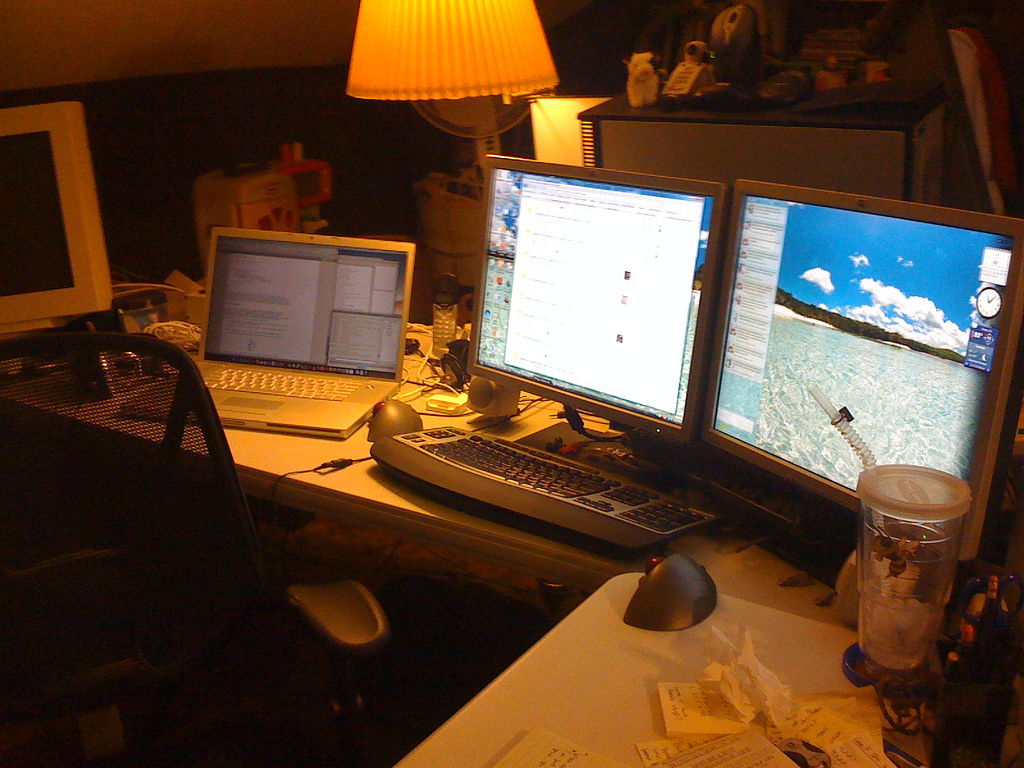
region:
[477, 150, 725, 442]
monitor is on a desk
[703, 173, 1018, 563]
monitor is on a desk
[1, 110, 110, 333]
monitor is on a desk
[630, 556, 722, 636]
mouse is gray and round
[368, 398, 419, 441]
mouse is gray and round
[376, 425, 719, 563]
keyboard is on a table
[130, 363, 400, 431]
keyboard is on a table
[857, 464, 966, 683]
plastic cup is on a table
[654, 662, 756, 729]
paper is on a table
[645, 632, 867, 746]
White receipt on the desk top.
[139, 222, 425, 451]
Silver open laptop on desk.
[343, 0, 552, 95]
White pleated lamp shade.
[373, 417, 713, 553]
Keyboard with black keys.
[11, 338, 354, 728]
Black computer chair.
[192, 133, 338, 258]
White sewing machine in corner.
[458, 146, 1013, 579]
Two monitors side by side turned on.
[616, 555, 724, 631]
A black computer mouse.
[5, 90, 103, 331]
An older white monitor.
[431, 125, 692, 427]
a white page is up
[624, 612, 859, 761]
receipts on the table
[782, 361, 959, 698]
the cup is clear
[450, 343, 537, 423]
the speaker is behind the monitor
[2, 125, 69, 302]
computer screen on the white desk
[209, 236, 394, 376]
computer screen on the white desk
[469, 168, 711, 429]
computer screen on the white desk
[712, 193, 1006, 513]
computer screen on the white desk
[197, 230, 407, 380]
computer screen on the white desk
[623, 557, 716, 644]
grey mouse on the white desk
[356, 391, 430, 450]
grey mouse on the white desk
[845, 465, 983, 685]
clear cup on the white desk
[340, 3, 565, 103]
large round white shade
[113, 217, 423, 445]
large silver square laptop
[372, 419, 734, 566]
long thin black keyboard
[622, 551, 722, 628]
large round black mouse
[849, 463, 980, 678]
tall clear plastic cup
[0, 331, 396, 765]
large black cloth chair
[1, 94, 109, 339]
large square white screen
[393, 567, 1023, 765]
large square white table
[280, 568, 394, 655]
thick black long arm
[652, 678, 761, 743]
small square white paper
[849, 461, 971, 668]
the cup is clear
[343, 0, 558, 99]
the lamp shade is white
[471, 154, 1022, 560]
the monitors are side by side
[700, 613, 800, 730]
the paper is crumpled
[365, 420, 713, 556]
the keyboard is black and gray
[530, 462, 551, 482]
A key on a keyboard.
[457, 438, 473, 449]
A key on a keyboard.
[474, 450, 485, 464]
A key on a keyboard.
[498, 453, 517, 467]
A key on a keyboard.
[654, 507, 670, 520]
A key on a keyboard.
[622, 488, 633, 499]
A key on a keyboard.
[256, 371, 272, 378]
A key on a keyboard.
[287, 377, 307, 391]
A key on a keyboard.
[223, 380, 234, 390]
A key on a keyboard.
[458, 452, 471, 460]
A key on a keyboard.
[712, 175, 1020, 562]
monitor next to monitor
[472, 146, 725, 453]
monitor next to monitor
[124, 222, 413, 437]
laptop turned on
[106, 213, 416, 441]
laptop between two monitors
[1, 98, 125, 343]
monitor to left of laptop